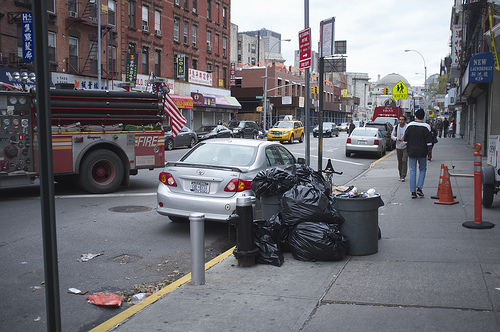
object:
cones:
[432, 167, 465, 216]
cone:
[435, 166, 460, 204]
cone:
[431, 162, 456, 199]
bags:
[251, 162, 348, 266]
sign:
[468, 51, 494, 82]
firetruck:
[0, 80, 165, 196]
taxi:
[266, 114, 306, 143]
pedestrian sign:
[391, 80, 408, 99]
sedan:
[157, 139, 310, 226]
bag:
[288, 220, 348, 262]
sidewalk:
[92, 135, 499, 331]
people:
[390, 107, 457, 200]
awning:
[458, 53, 492, 102]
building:
[0, 0, 243, 136]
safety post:
[462, 142, 495, 229]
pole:
[397, 99, 400, 123]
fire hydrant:
[229, 193, 259, 267]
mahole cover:
[107, 204, 151, 213]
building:
[370, 72, 411, 94]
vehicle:
[345, 125, 385, 157]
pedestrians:
[392, 107, 432, 198]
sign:
[21, 13, 34, 63]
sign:
[298, 26, 311, 70]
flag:
[161, 91, 187, 141]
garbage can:
[331, 191, 385, 257]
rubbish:
[85, 291, 120, 308]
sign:
[187, 69, 214, 84]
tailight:
[159, 172, 177, 187]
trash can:
[261, 193, 281, 220]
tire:
[77, 149, 124, 193]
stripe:
[52, 137, 74, 151]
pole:
[303, 0, 310, 167]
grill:
[269, 129, 288, 135]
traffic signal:
[311, 86, 320, 95]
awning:
[166, 94, 194, 110]